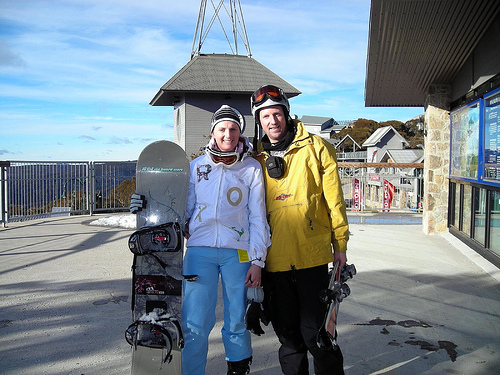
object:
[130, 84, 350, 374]
couple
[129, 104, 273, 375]
woman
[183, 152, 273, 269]
white jacket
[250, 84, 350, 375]
man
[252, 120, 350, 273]
yellow jacket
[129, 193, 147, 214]
glove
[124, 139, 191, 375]
snowboard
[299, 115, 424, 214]
houses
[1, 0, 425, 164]
sky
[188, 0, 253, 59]
tower base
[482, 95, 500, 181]
schedule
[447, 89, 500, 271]
window]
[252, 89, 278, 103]
goggles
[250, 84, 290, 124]
helmet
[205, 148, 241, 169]
white goggles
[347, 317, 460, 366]
stain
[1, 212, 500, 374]
pavement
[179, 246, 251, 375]
snowpants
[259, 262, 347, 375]
pants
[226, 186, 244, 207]
o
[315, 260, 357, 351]
skis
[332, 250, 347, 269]
hand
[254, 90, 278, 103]
red lenses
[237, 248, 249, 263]
ski lift ticket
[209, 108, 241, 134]
hat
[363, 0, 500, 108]
eave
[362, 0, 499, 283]
building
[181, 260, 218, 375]
leg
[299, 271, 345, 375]
leg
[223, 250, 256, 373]
leg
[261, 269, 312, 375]
leg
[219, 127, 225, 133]
eye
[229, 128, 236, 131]
left eye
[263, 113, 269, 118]
right eye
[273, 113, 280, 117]
left eye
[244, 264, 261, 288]
left hand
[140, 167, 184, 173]
green print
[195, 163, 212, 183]
design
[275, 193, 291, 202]
logo